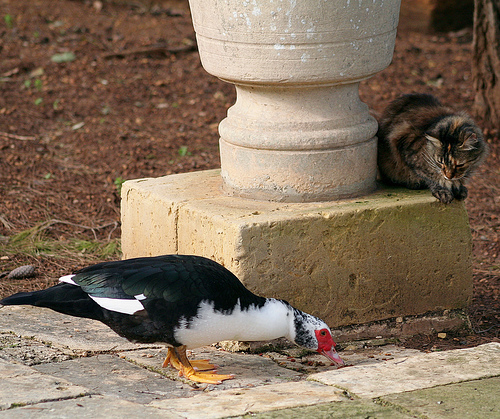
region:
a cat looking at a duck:
[22, 46, 491, 401]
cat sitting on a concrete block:
[375, 80, 499, 321]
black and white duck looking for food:
[17, 228, 354, 391]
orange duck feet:
[145, 333, 238, 393]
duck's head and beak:
[285, 293, 352, 375]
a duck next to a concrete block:
[2, 199, 496, 392]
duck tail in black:
[3, 244, 109, 349]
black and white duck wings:
[58, 262, 215, 332]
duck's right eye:
[298, 310, 345, 372]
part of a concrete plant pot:
[175, 1, 385, 194]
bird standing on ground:
[8, 194, 378, 414]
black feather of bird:
[17, 225, 274, 356]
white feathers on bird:
[159, 300, 310, 370]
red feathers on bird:
[309, 320, 390, 385]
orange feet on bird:
[143, 339, 235, 396]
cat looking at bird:
[0, 60, 499, 393]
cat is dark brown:
[353, 63, 495, 231]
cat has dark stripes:
[372, 80, 488, 224]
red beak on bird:
[318, 345, 343, 372]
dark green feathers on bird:
[68, 250, 196, 327]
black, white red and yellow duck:
[3, 248, 338, 385]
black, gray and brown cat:
[376, 89, 486, 205]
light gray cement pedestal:
[118, 162, 476, 327]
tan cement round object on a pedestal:
[184, 1, 406, 192]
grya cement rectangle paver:
[121, 332, 306, 393]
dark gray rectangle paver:
[26, 345, 205, 403]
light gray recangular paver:
[310, 339, 497, 397]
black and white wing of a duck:
[56, 253, 216, 313]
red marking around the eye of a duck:
[310, 326, 337, 358]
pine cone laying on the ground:
[5, 261, 39, 280]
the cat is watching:
[372, 78, 496, 210]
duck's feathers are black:
[40, 248, 250, 361]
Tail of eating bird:
[54, 265, 101, 301]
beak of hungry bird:
[319, 347, 349, 372]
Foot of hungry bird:
[183, 369, 249, 386]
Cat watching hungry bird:
[418, 114, 490, 182]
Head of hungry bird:
[289, 307, 350, 369]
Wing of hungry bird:
[54, 262, 177, 315]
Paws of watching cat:
[422, 183, 473, 204]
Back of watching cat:
[397, 99, 434, 123]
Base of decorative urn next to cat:
[210, 86, 382, 200]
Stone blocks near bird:
[261, 379, 392, 417]